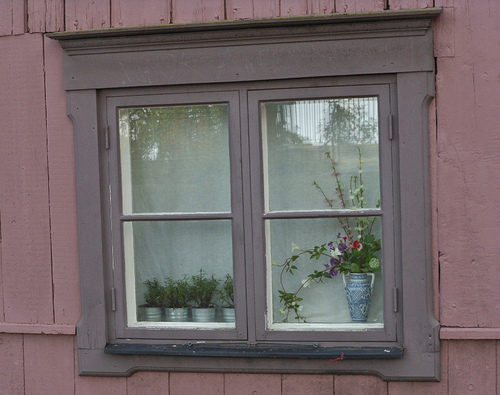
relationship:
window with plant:
[66, 12, 453, 376] [272, 146, 378, 321]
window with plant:
[66, 12, 453, 376] [133, 270, 230, 306]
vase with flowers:
[341, 270, 374, 322] [286, 140, 382, 276]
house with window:
[0, 1, 500, 390] [66, 12, 453, 376]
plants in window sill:
[140, 270, 236, 324] [111, 330, 409, 368]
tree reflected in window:
[123, 110, 223, 182] [100, 73, 394, 344]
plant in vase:
[272, 146, 378, 321] [343, 271, 377, 324]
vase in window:
[341, 270, 374, 322] [256, 95, 386, 329]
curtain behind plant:
[148, 121, 236, 264] [141, 271, 161, 316]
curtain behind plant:
[148, 121, 236, 264] [163, 273, 187, 315]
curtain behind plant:
[148, 121, 236, 264] [191, 272, 214, 322]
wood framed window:
[48, 5, 441, 84] [36, 13, 456, 392]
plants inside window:
[139, 271, 169, 323] [42, 22, 442, 380]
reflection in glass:
[261, 93, 385, 210] [133, 96, 378, 323]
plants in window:
[146, 204, 381, 331] [66, 12, 453, 376]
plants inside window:
[136, 143, 381, 333] [100, 73, 394, 344]